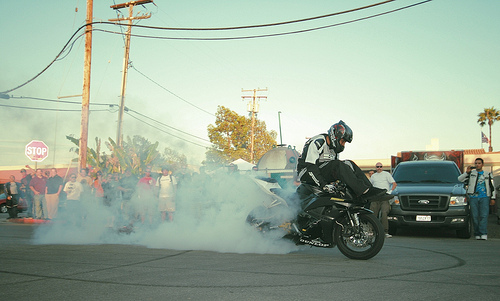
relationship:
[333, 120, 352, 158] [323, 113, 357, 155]
man has helmet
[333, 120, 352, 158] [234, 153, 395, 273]
man riding bike